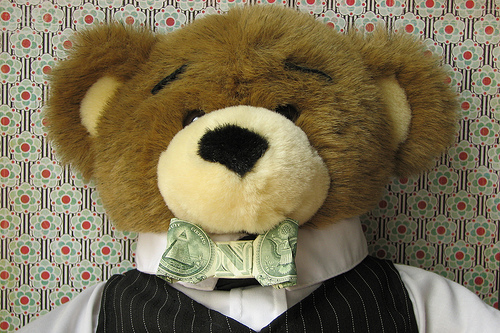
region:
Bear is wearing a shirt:
[11, 226, 498, 330]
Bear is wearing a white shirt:
[12, 217, 497, 331]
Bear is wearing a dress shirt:
[6, 213, 498, 330]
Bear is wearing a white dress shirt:
[8, 213, 497, 330]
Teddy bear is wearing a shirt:
[6, 213, 496, 329]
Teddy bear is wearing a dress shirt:
[10, 211, 496, 331]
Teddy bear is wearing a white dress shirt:
[10, 211, 497, 330]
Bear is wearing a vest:
[95, 254, 421, 331]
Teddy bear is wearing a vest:
[97, 255, 426, 330]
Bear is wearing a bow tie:
[153, 212, 308, 292]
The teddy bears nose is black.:
[192, 125, 264, 175]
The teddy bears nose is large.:
[196, 121, 271, 173]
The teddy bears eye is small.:
[178, 105, 201, 126]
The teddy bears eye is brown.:
[181, 106, 202, 123]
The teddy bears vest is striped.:
[333, 286, 403, 328]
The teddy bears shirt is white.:
[420, 288, 462, 326]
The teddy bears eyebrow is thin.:
[285, 55, 332, 85]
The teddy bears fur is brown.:
[203, 25, 264, 67]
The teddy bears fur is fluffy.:
[214, 25, 271, 82]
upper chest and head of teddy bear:
[0, 3, 498, 328]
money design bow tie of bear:
[157, 216, 307, 288]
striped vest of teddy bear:
[90, 275, 415, 331]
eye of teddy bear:
[172, 108, 211, 128]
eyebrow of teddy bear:
[136, 63, 201, 90]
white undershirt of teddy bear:
[405, 260, 499, 328]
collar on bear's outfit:
[298, 231, 365, 266]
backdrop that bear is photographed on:
[4, 148, 51, 301]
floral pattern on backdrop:
[22, 211, 65, 238]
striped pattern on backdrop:
[458, 73, 471, 88]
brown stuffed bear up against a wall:
[1, 3, 497, 331]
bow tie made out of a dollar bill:
[155, 215, 300, 285]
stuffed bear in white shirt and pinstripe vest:
[16, 1, 496, 327]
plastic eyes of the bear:
[180, 100, 300, 125]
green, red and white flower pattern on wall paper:
[425, 211, 455, 241]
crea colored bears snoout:
[155, 101, 330, 227]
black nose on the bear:
[196, 120, 266, 175]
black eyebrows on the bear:
[146, 56, 327, 91]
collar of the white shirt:
[132, 215, 374, 285]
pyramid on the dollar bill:
[162, 227, 192, 263]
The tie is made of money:
[151, 212, 301, 292]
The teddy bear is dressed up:
[12, 22, 477, 320]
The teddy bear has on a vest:
[121, 296, 412, 331]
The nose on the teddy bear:
[193, 122, 270, 178]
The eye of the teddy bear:
[170, 96, 216, 126]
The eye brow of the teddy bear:
[136, 55, 201, 93]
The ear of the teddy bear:
[37, 18, 154, 186]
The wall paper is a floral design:
[3, 28, 50, 313]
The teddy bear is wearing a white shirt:
[421, 270, 493, 331]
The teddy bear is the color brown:
[108, 40, 368, 117]